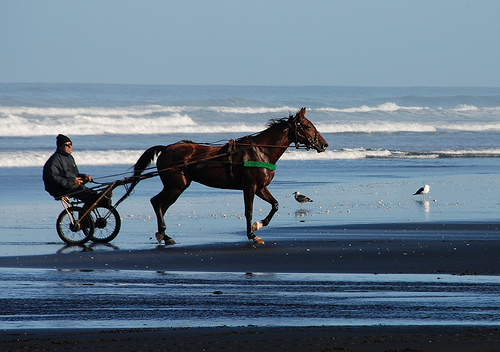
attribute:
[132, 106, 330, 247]
horse — running, brown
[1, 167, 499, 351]
beach — wet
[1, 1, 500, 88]
sky — blue, cloudless, white-cloudless, white-cloud-less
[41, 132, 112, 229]
man — sitting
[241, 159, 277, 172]
strap — green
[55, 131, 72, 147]
stocking cap — black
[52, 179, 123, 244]
carriage — small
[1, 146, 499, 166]
waves — white-capped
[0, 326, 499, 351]
part — dry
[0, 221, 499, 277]
part — dry